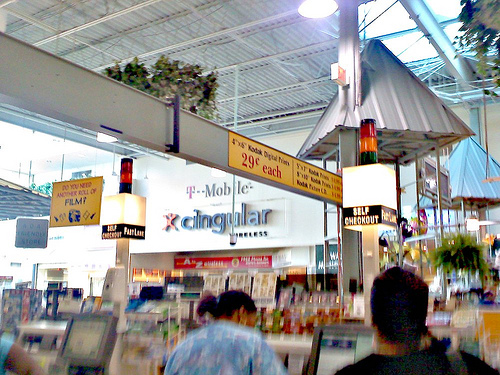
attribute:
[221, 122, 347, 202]
sign — yellow, red, ad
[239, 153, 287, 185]
numbers — red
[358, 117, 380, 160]
lights — multicolor, red,orange, green, red, yellow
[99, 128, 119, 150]
light — glowing, white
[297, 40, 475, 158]
roof — pointed, gray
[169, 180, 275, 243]
logos — stacked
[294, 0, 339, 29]
light — round, glowing, mounted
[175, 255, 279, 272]
sign — rectanglular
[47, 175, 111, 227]
sign — yellow, square, hanging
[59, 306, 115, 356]
cash register — screen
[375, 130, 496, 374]
store — open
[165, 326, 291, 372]
shirt — blue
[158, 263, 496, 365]
people — local, shopping, spending, out, standing